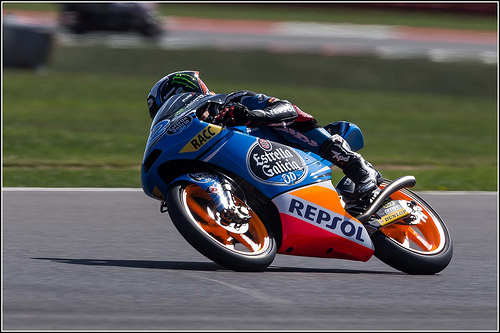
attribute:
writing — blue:
[286, 196, 366, 243]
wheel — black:
[353, 175, 450, 275]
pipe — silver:
[323, 165, 415, 234]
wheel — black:
[162, 179, 279, 272]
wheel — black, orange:
[348, 173, 453, 273]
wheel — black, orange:
[167, 172, 270, 264]